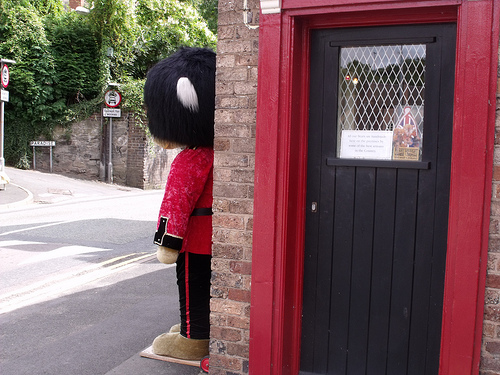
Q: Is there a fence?
A: No, there are no fences.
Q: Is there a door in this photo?
A: Yes, there is a door.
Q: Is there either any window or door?
A: Yes, there is a door.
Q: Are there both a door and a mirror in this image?
A: No, there is a door but no mirrors.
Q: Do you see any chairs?
A: No, there are no chairs.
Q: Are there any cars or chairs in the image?
A: No, there are no chairs or cars.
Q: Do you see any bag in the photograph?
A: No, there are no bags.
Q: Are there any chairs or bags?
A: No, there are no bags or chairs.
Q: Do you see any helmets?
A: Yes, there is a helmet.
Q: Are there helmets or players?
A: Yes, there is a helmet.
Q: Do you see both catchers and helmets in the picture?
A: No, there is a helmet but no catchers.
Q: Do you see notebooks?
A: No, there are no notebooks.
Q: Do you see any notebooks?
A: No, there are no notebooks.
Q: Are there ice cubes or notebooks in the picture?
A: No, there are no notebooks or ice cubes.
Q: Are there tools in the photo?
A: No, there are no tools.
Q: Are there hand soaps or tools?
A: No, there are no tools or hand soaps.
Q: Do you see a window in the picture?
A: Yes, there is a window.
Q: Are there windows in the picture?
A: Yes, there is a window.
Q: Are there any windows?
A: Yes, there is a window.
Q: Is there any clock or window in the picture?
A: Yes, there is a window.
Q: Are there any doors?
A: Yes, there is a door.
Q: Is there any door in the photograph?
A: Yes, there is a door.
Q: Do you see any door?
A: Yes, there is a door.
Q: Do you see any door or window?
A: Yes, there is a door.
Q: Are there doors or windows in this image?
A: Yes, there is a door.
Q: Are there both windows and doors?
A: Yes, there are both a door and a window.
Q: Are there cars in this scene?
A: No, there are no cars.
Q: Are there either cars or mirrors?
A: No, there are no cars or mirrors.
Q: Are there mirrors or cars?
A: No, there are no cars or mirrors.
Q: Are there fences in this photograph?
A: No, there are no fences.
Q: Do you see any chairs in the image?
A: No, there are no chairs.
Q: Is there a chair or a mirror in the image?
A: No, there are no chairs or mirrors.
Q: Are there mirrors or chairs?
A: No, there are no chairs or mirrors.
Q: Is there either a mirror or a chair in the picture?
A: No, there are no chairs or mirrors.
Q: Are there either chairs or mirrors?
A: No, there are no chairs or mirrors.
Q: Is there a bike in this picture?
A: No, there are no bikes.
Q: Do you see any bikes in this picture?
A: No, there are no bikes.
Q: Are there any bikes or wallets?
A: No, there are no bikes or wallets.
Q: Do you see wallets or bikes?
A: No, there are no bikes or wallets.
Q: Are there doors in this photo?
A: Yes, there is a door.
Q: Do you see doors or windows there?
A: Yes, there is a door.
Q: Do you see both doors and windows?
A: Yes, there are both a door and windows.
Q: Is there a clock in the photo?
A: No, there are no clocks.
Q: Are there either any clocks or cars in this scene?
A: No, there are no clocks or cars.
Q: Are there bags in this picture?
A: No, there are no bags.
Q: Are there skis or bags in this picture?
A: No, there are no bags or skis.